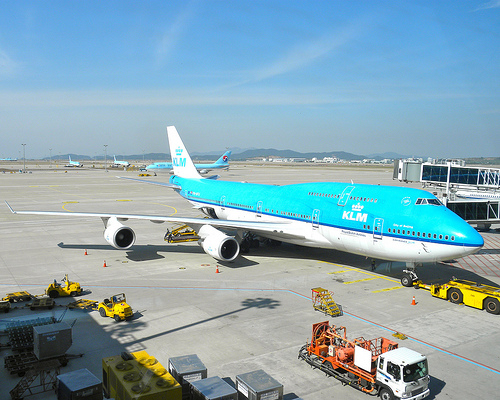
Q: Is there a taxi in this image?
A: Yes, there is a taxi.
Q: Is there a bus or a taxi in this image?
A: Yes, there is a taxi.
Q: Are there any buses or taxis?
A: Yes, there is a taxi.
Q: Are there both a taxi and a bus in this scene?
A: No, there is a taxi but no buses.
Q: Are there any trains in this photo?
A: No, there are no trains.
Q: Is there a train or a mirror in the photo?
A: No, there are no trains or mirrors.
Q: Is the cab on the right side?
A: Yes, the cab is on the right of the image.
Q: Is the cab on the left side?
A: No, the cab is on the right of the image.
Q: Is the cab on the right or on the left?
A: The cab is on the right of the image.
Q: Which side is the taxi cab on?
A: The taxi cab is on the right of the image.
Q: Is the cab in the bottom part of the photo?
A: Yes, the cab is in the bottom of the image.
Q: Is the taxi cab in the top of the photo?
A: No, the taxi cab is in the bottom of the image.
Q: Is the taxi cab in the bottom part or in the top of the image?
A: The taxi cab is in the bottom of the image.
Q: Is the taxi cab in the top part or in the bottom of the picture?
A: The taxi cab is in the bottom of the image.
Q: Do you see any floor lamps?
A: No, there are no floor lamps.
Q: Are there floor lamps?
A: No, there are no floor lamps.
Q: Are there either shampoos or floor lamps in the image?
A: No, there are no floor lamps or shampoos.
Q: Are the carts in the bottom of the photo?
A: Yes, the carts are in the bottom of the image.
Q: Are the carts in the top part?
A: No, the carts are in the bottom of the image.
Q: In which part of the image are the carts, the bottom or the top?
A: The carts are in the bottom of the image.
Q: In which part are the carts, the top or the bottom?
A: The carts are in the bottom of the image.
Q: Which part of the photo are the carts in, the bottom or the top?
A: The carts are in the bottom of the image.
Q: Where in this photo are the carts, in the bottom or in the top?
A: The carts are in the bottom of the image.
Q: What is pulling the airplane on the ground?
A: The carts are pulling the airplane.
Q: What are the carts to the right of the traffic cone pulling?
A: The carts are pulling the plane.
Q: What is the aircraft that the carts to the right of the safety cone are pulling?
A: The aircraft is an airplane.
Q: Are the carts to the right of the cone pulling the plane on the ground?
A: Yes, the carts are pulling the airplane.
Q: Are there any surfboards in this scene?
A: No, there are no surfboards.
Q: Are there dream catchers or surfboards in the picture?
A: No, there are no surfboards or dream catchers.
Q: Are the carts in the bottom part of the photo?
A: Yes, the carts are in the bottom of the image.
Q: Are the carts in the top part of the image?
A: No, the carts are in the bottom of the image.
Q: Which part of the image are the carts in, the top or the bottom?
A: The carts are in the bottom of the image.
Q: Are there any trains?
A: No, there are no trains.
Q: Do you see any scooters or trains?
A: No, there are no trains or scooters.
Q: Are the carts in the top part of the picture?
A: No, the carts are in the bottom of the image.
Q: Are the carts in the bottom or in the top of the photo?
A: The carts are in the bottom of the image.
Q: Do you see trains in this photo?
A: No, there are no trains.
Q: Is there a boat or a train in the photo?
A: No, there are no trains or boats.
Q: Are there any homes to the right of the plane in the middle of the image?
A: Yes, there are homes to the right of the plane.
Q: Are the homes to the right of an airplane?
A: Yes, the homes are to the right of an airplane.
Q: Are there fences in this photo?
A: No, there are no fences.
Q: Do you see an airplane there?
A: Yes, there is an airplane.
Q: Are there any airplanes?
A: Yes, there is an airplane.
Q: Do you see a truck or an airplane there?
A: Yes, there is an airplane.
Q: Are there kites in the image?
A: No, there are no kites.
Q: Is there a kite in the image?
A: No, there are no kites.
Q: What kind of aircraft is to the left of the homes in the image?
A: The aircraft is an airplane.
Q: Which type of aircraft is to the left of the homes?
A: The aircraft is an airplane.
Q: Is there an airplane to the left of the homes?
A: Yes, there is an airplane to the left of the homes.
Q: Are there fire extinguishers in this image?
A: No, there are no fire extinguishers.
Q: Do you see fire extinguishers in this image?
A: No, there are no fire extinguishers.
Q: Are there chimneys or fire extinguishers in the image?
A: No, there are no fire extinguishers or chimneys.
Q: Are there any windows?
A: Yes, there are windows.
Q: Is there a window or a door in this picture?
A: Yes, there are windows.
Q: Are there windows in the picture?
A: Yes, there are windows.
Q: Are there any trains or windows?
A: Yes, there are windows.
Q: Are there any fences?
A: No, there are no fences.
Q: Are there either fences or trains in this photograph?
A: No, there are no fences or trains.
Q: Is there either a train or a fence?
A: No, there are no fences or trains.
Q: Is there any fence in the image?
A: No, there are no fences.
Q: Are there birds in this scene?
A: No, there are no birds.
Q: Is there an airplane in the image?
A: Yes, there is an airplane.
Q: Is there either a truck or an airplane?
A: Yes, there is an airplane.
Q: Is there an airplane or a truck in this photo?
A: Yes, there is an airplane.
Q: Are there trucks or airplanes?
A: Yes, there is an airplane.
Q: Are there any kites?
A: No, there are no kites.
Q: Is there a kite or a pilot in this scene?
A: No, there are no kites or pilots.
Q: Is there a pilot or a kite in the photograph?
A: No, there are no kites or pilots.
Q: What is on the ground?
A: The plane is on the ground.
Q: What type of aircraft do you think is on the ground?
A: The aircraft is an airplane.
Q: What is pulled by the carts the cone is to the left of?
A: The airplane is pulled by the carts.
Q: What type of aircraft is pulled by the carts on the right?
A: The aircraft is an airplane.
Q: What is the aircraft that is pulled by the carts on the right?
A: The aircraft is an airplane.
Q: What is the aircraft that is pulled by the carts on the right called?
A: The aircraft is an airplane.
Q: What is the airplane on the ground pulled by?
A: The airplane is pulled by the carts.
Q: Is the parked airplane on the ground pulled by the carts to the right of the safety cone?
A: Yes, the plane is pulled by the carts.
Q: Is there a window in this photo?
A: Yes, there are windows.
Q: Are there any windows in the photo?
A: Yes, there are windows.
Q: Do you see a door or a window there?
A: Yes, there are windows.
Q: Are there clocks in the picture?
A: No, there are no clocks.